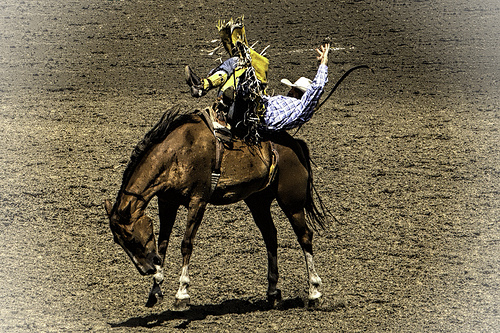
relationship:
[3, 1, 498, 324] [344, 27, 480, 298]
dirt in arena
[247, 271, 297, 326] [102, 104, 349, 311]
hoof on horse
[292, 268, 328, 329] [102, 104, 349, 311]
hoof on horse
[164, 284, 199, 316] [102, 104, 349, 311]
hoof on horse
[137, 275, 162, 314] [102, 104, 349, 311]
hoof on horse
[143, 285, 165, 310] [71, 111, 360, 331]
hoof on horse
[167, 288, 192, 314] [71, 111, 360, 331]
hoof on horse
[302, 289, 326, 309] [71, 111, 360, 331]
hoof on horse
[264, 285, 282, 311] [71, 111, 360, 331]
hoof on horse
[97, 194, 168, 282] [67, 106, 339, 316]
head on horse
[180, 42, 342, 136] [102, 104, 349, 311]
cowboy on horse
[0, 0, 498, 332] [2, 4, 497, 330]
dirt in arena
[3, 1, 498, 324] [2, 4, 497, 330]
dirt in arena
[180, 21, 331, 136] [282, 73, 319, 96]
cowboy wearing hat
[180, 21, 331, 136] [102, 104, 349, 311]
cowboy on horse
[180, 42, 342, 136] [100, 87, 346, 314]
cowboy on horse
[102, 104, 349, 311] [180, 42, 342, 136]
horse throwing cowboy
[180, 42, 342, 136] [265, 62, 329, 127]
cowboy wearing shirt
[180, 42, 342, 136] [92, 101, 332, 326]
cowboy being thrown off horse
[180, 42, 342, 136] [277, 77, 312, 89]
cowboy wearing hat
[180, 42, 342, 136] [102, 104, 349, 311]
cowboy being thrown from horse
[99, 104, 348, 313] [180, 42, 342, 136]
horse bucking off cowboy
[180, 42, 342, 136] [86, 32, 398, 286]
cowboy on horse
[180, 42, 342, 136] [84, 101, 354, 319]
cowboy on horse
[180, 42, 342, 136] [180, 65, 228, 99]
cowboy wearing boot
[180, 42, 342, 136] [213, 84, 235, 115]
cowboy wearing boot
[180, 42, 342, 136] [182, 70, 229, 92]
cowboy wearing shoe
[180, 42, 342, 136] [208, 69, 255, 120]
cowboy wearing shoe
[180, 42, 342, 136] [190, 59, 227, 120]
cowboy wearing boots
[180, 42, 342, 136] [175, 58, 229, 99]
cowboy wearing boot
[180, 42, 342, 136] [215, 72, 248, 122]
cowboy wearing boot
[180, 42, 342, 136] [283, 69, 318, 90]
cowboy wearing hat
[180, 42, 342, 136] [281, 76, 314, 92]
cowboy wearing hat